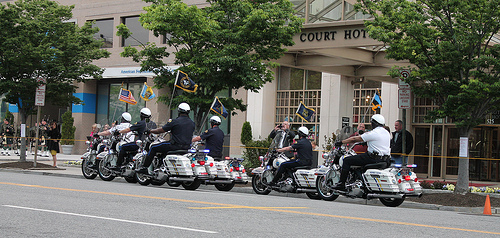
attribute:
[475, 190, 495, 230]
cone — orange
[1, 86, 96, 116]
stripe — blue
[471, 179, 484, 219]
cone — orange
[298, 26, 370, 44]
letters — black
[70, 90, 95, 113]
paint — blue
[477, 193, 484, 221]
cone — orange